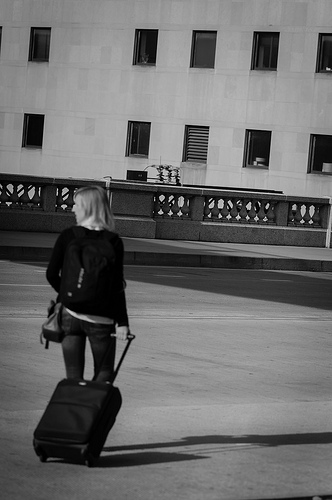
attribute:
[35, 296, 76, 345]
handbag — small, leather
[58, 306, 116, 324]
shirt — white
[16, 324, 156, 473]
suitcase — large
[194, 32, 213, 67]
glass — square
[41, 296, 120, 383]
jeans — dark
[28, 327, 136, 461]
suitcase — black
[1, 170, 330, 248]
wall — stone, short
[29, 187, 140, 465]
woman — walking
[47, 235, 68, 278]
jacket — dark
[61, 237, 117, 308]
backpack — black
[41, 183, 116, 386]
woman — blonde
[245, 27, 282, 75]
building window — square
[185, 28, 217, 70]
building window — square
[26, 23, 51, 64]
building window — square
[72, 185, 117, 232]
hair — blonde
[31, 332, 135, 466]
suitcase — black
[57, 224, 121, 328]
backpack — black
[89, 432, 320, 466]
shadow — dark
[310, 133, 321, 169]
glass — square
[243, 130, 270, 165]
glass — square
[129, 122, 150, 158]
glass — square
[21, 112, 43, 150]
glass — square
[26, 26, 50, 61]
glass — square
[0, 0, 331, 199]
building — large, stone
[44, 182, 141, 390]
woman — blonde